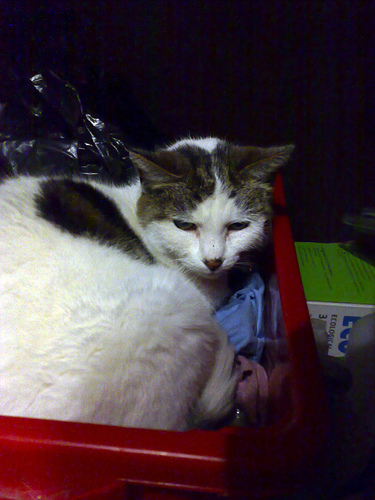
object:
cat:
[0, 135, 295, 432]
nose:
[203, 255, 222, 271]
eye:
[173, 215, 197, 232]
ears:
[127, 142, 295, 185]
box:
[0, 138, 328, 500]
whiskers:
[150, 249, 253, 278]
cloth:
[210, 270, 267, 367]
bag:
[1, 50, 137, 190]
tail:
[64, 338, 239, 429]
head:
[123, 136, 295, 279]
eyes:
[227, 219, 250, 231]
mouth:
[201, 266, 227, 281]